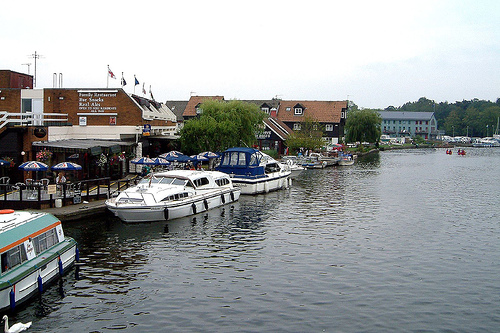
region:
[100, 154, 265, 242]
boat on the water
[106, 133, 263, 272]
the boat is white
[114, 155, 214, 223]
the boat is white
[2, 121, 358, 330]
boats docked next to pier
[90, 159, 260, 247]
white boat at pier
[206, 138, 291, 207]
white and blue boat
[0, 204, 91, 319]
green and white boat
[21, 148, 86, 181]
blue and white umbrella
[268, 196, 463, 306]
water is dark green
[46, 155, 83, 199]
person sitting under umbrella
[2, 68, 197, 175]
brown building in background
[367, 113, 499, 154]
multiple cars parked in background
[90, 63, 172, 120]
flags on top of building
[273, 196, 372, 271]
the water is calm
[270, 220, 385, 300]
the water is calm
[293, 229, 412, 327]
the water is calm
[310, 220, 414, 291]
the water is calm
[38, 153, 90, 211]
a man sitting under the umbrella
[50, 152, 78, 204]
a man sitting under the umbrella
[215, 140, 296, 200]
Blue and white boat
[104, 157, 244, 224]
White and black boat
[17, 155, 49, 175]
White and blue umbrella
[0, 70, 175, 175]
White and brick building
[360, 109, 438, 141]
White building in background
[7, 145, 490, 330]
Black body of water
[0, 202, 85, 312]
White, blue and orange boat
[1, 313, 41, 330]
White swan in water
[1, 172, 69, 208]
Seating area of restaurant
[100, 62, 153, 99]
Flags on top of building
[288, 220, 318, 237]
ripple in the water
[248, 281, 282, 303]
ripple in the water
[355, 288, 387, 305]
ripple in the water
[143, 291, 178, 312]
ripple in the water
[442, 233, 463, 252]
ripple in the water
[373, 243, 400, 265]
ripple in the water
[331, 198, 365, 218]
ripple in the water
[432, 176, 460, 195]
ripple in the water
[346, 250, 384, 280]
ripple in the water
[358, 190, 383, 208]
ripple in the water